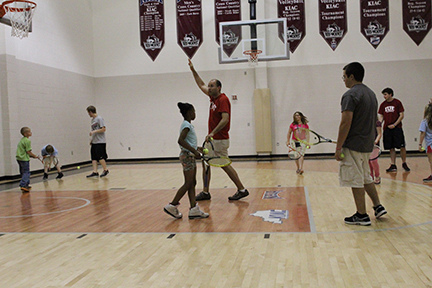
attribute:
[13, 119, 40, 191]
boy — young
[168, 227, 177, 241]
line — black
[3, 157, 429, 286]
court — wood, tan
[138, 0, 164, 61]
banner — championship banner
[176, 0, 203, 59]
banner — championship banner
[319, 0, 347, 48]
banner — championship banner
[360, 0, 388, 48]
banner — championship banner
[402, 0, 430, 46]
banner — championship banner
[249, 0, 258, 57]
pole — black, metal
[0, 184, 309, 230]
square — red, wood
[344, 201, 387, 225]
tennis shoes — black, white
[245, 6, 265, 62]
pole — black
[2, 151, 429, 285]
floor — wooden 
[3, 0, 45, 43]
basketball netting — white 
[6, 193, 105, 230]
lines — white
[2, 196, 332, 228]
wood — red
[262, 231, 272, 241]
line — black, tape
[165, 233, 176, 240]
line — black, tape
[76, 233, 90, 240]
line — black, tape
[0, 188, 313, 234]
square — red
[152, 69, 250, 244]
man — balding